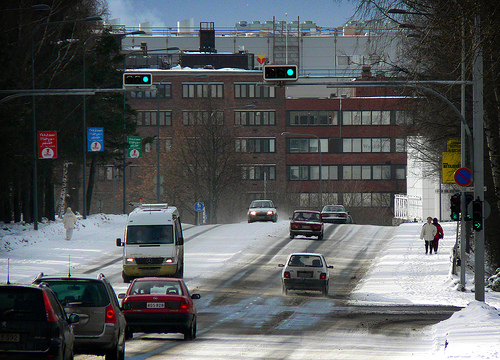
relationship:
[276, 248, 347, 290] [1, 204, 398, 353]
car on street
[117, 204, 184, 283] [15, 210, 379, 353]
truck on street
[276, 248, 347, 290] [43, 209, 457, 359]
car on street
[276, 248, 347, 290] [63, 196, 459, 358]
car on street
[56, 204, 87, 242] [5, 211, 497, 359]
pedestrian in snow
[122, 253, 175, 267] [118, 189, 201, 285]
headlights on van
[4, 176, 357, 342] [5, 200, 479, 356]
city traffic on street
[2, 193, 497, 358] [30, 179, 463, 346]
snow covering city street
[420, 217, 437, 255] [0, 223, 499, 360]
people driving on city street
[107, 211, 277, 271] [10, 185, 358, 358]
headlights on cars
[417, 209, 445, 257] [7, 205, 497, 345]
people walking in snow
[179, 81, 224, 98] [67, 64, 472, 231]
windows on building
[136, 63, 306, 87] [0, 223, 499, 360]
green lights on city street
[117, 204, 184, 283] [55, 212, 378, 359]
truck on road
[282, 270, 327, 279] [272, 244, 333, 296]
red lights on car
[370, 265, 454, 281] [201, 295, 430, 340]
black shadow on ground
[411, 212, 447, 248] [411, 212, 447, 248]
people are walking walk people are walking